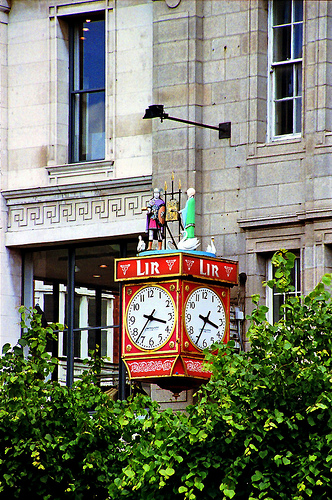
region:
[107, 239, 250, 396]
Clock with red box and a white face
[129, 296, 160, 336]
Black hands on the clock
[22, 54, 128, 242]
Cream colored stone building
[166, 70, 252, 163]
Grey colored stone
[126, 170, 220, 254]
Mini-statues on top of clock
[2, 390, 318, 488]
Foilage in front of the clock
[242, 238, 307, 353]
The white frame of the window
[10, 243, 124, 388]
Black window frames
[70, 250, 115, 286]
Recessed lighting on the cieling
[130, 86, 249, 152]
A black lamp post coming out of the wall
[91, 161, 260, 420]
lir clock in dublin, ireland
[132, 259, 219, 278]
'lir', in all caps, on two visible sides of clock [likely on at least three of four]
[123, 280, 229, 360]
it is now, on the clock in lir, 3:36pm or 3:37pm- the clocks are a bit off, each to each, but it is daylight so it's not a little before 4am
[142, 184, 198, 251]
statues are meant to represent the story of the children of lir, who were turned into swans for 900 years.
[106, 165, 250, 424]
locals are very much of two minds about this clock. if yr clever, yr supposed to hate it.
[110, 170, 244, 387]
clever interpretation: gaudy, ghastly mechanized art nouveau rendition of Irish myth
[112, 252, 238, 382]
it's red, with gilded appointments [dont know if paint or leaf, likely paint] & sits on a thick metal pole, i'll give it that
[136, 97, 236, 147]
peculiarly modern lamp above it to set it off at night, i guess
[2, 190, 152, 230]
greek key sort of decoration on modern building behind, really mixing it up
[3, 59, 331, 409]
modern building in back is just as weatherbeat as the clock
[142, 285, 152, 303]
black number on clock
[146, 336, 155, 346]
black number on clock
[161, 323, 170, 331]
black number on clock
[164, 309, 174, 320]
black number on clock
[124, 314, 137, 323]
black number on clock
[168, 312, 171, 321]
black number on clock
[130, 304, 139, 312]
black number on clock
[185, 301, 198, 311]
black number on clock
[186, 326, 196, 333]
black number on clock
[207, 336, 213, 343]
black number on clock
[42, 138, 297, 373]
a building with a clock in front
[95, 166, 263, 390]
this is a decorative clock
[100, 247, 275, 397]
the time on this clock is 3:37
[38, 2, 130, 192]
the window is on the building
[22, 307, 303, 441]
lots of shrubbery surrounds the clock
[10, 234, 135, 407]
a window in the building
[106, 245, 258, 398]
the clock is red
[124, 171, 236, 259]
these are figurines on the clock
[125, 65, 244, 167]
a protruding light on the building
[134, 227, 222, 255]
small duck figurines on the clock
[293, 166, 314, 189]
part of a wall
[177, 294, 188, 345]
edge of a clock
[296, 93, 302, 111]
part of a window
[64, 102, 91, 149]
edge of a window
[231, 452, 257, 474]
tip of a leaf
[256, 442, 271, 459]
edge of a bush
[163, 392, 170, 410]
part of the wall